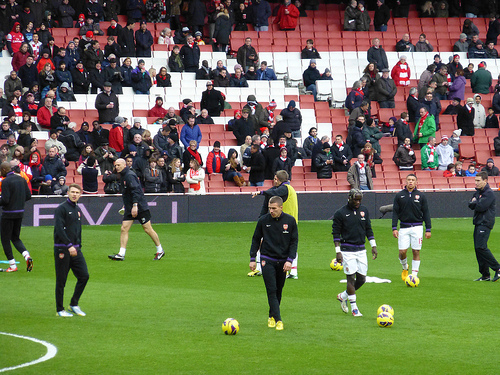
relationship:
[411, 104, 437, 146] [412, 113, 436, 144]
man wearing jacket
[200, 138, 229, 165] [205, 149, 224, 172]
person wearing jacket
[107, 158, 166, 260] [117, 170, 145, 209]
man wearing jacket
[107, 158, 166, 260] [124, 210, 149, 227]
man wearing shorts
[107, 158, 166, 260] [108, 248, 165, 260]
man wearing shoes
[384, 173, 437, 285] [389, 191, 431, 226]
man wearing jacket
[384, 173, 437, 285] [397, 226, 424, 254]
man wearing shorts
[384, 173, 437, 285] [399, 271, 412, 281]
man wearing shoes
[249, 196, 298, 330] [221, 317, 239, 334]
man looking at ball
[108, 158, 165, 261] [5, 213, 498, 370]
man on field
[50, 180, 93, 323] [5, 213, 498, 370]
players on field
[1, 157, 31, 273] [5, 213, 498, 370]
players on field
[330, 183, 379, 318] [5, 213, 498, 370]
players on field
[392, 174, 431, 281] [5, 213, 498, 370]
man on field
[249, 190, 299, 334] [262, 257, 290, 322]
man wearing pants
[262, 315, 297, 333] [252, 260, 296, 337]
shoes on feet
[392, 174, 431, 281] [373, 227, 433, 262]
man wearing shorts